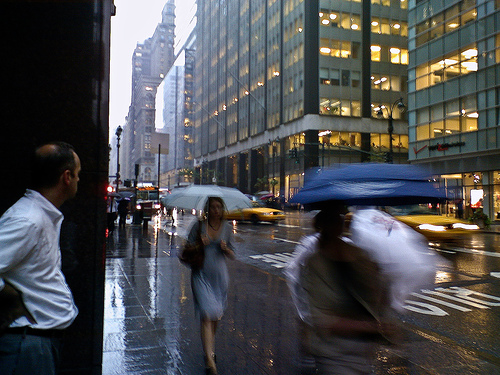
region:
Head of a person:
[21, 133, 90, 211]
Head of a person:
[197, 191, 232, 222]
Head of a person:
[303, 184, 377, 267]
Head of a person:
[122, 171, 134, 191]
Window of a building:
[312, 89, 368, 123]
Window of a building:
[318, 35, 369, 65]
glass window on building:
[461, 111, 478, 132]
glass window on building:
[443, 114, 460, 137]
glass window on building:
[428, 120, 443, 139]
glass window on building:
[414, 123, 430, 143]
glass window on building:
[456, 57, 477, 73]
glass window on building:
[441, 64, 462, 77]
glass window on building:
[426, 68, 443, 84]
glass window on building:
[413, 73, 428, 93]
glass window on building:
[458, 40, 478, 60]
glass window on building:
[443, 50, 460, 66]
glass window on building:
[414, 62, 426, 74]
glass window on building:
[428, 55, 443, 70]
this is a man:
[3, 120, 112, 372]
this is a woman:
[142, 132, 283, 370]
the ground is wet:
[116, 136, 497, 373]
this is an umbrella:
[154, 160, 254, 247]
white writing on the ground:
[259, 228, 497, 340]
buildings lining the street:
[118, 0, 492, 211]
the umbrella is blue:
[283, 148, 455, 228]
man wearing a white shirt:
[3, 173, 83, 342]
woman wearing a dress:
[177, 208, 242, 335]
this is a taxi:
[210, 183, 293, 235]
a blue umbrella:
[285, 162, 449, 216]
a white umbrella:
[155, 177, 250, 215]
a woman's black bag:
[177, 216, 208, 273]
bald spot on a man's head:
[34, 138, 59, 162]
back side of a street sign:
[147, 130, 172, 158]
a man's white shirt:
[1, 185, 81, 335]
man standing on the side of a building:
[0, 135, 93, 371]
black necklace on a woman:
[203, 217, 224, 232]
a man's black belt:
[8, 321, 61, 344]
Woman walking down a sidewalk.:
[160, 173, 253, 371]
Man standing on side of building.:
[0, 128, 109, 370]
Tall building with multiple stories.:
[186, 3, 411, 183]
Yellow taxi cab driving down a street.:
[221, 191, 287, 229]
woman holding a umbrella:
[151, 172, 247, 342]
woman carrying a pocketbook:
[178, 215, 210, 284]